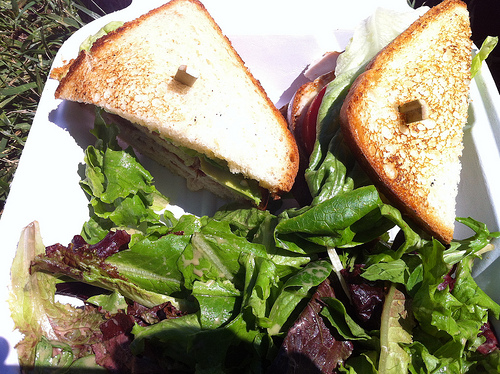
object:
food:
[44, 21, 477, 233]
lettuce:
[9, 107, 497, 370]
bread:
[338, 0, 472, 246]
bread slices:
[284, 0, 467, 245]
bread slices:
[55, 1, 298, 190]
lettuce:
[299, 89, 445, 278]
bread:
[48, 2, 488, 252]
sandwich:
[54, 0, 300, 205]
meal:
[91, 16, 489, 363]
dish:
[10, 12, 478, 372]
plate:
[4, 1, 497, 369]